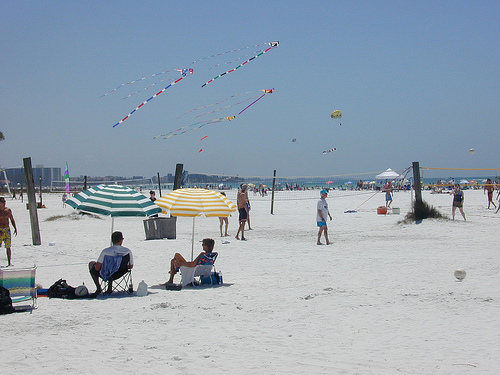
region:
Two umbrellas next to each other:
[61, 177, 265, 243]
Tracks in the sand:
[270, 275, 387, 344]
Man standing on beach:
[302, 169, 346, 266]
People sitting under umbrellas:
[64, 215, 261, 301]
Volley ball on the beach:
[448, 264, 473, 288]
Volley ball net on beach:
[172, 159, 466, 226]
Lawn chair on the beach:
[2, 264, 46, 319]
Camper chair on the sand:
[95, 252, 153, 294]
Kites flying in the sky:
[93, 35, 377, 152]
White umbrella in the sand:
[374, 158, 411, 209]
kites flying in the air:
[87, 11, 397, 173]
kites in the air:
[108, 27, 451, 177]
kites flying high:
[91, 22, 394, 177]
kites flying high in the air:
[94, 20, 471, 156]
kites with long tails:
[62, 18, 400, 206]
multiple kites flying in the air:
[93, 20, 386, 162]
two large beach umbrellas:
[57, 155, 272, 321]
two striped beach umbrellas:
[60, 123, 301, 264]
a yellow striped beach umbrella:
[144, 157, 289, 302]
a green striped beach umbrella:
[67, 146, 170, 323]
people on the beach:
[1, 173, 421, 331]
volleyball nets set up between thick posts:
[22, 152, 499, 229]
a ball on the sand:
[435, 256, 478, 295]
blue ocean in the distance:
[163, 174, 490, 189]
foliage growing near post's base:
[402, 164, 446, 226]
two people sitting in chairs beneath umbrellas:
[61, 178, 236, 306]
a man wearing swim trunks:
[0, 190, 27, 270]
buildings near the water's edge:
[2, 164, 267, 196]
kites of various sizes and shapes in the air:
[78, 26, 387, 204]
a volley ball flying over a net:
[429, 137, 496, 196]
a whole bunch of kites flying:
[81, 37, 353, 163]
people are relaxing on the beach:
[36, 205, 387, 337]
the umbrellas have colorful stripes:
[55, 127, 262, 250]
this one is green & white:
[65, 168, 156, 235]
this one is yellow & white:
[163, 174, 238, 249]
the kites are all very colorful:
[123, 8, 367, 168]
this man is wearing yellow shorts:
[1, 188, 38, 303]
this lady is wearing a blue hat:
[311, 175, 348, 246]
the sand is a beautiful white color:
[273, 247, 423, 279]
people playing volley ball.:
[386, 141, 498, 218]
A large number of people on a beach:
[0, 177, 492, 359]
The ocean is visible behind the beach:
[162, 173, 482, 180]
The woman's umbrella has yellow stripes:
[160, 187, 234, 220]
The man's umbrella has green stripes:
[71, 183, 160, 219]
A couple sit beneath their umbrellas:
[60, 177, 239, 285]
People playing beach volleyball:
[446, 177, 496, 222]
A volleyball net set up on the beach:
[407, 162, 498, 186]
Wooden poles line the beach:
[20, 155, 44, 247]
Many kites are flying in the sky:
[112, 28, 286, 151]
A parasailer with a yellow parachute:
[324, 105, 350, 132]